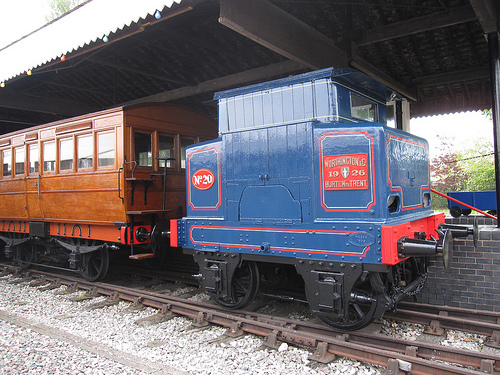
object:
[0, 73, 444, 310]
train cars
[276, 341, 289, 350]
gravels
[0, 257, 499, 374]
railroad tracks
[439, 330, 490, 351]
gravel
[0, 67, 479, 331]
train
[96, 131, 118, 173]
window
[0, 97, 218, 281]
car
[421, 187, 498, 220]
object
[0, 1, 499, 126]
roof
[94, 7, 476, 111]
beams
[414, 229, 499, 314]
wall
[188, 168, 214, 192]
sign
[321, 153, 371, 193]
sign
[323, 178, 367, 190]
text